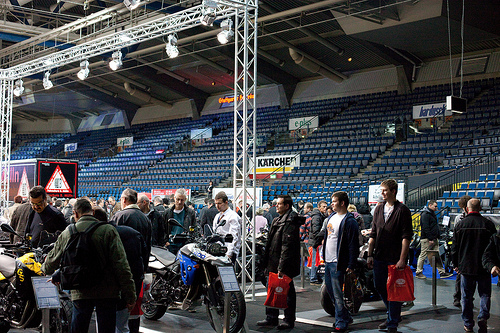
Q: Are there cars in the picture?
A: No, there are no cars.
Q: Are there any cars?
A: No, there are no cars.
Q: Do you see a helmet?
A: No, there are no helmets.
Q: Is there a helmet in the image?
A: No, there are no helmets.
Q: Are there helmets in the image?
A: No, there are no helmets.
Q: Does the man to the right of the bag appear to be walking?
A: Yes, the man is walking.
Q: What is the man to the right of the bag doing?
A: The man is walking.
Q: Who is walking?
A: The man is walking.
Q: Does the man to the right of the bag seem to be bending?
A: No, the man is walking.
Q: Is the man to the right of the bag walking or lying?
A: The man is walking.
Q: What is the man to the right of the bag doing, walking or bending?
A: The man is walking.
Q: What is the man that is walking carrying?
A: The man is carrying a bag.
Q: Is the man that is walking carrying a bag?
A: Yes, the man is carrying a bag.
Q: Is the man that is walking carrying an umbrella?
A: No, the man is carrying a bag.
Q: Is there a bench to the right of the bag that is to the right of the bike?
A: No, there is a man to the right of the bag.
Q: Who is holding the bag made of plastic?
A: The man is holding the bag.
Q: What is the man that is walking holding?
A: The man is holding the bag.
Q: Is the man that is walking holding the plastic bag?
A: Yes, the man is holding the bag.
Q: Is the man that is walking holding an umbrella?
A: No, the man is holding the bag.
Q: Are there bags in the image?
A: Yes, there is a bag.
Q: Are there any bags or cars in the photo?
A: Yes, there is a bag.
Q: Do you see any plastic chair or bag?
A: Yes, there is a plastic bag.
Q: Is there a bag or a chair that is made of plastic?
A: Yes, the bag is made of plastic.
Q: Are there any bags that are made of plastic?
A: Yes, there is a bag that is made of plastic.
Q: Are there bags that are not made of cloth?
A: Yes, there is a bag that is made of plastic.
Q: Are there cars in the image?
A: No, there are no cars.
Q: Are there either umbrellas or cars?
A: No, there are no cars or umbrellas.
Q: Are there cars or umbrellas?
A: No, there are no cars or umbrellas.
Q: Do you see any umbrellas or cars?
A: No, there are no cars or umbrellas.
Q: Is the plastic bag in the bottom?
A: Yes, the bag is in the bottom of the image.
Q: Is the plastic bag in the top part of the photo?
A: No, the bag is in the bottom of the image.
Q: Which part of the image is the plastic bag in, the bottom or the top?
A: The bag is in the bottom of the image.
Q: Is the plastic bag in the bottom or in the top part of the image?
A: The bag is in the bottom of the image.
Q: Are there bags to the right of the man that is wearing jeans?
A: Yes, there is a bag to the right of the man.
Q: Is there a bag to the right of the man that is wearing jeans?
A: Yes, there is a bag to the right of the man.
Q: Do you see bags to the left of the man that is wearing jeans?
A: No, the bag is to the right of the man.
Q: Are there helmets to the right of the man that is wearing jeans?
A: No, there is a bag to the right of the man.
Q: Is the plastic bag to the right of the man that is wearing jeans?
A: Yes, the bag is to the right of the man.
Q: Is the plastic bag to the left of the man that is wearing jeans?
A: No, the bag is to the right of the man.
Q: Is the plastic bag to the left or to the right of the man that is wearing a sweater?
A: The bag is to the right of the man.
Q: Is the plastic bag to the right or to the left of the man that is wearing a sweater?
A: The bag is to the right of the man.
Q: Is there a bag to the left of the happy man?
A: No, the bag is to the right of the man.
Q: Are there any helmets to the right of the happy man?
A: No, there is a bag to the right of the man.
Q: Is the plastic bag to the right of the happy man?
A: Yes, the bag is to the right of the man.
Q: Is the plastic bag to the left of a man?
A: No, the bag is to the right of a man.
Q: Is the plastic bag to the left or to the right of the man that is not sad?
A: The bag is to the right of the man.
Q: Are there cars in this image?
A: No, there are no cars.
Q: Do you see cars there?
A: No, there are no cars.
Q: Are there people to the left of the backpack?
A: Yes, there are people to the left of the backpack.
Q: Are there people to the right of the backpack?
A: No, the people are to the left of the backpack.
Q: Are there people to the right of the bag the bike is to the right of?
A: No, the people are to the left of the backpack.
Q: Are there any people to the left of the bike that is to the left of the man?
A: Yes, there are people to the left of the bike.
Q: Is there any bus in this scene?
A: No, there are no buses.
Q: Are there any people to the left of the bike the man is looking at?
A: Yes, there is a person to the left of the bike.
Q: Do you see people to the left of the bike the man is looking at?
A: Yes, there is a person to the left of the bike.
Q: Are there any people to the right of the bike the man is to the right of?
A: No, the person is to the left of the bike.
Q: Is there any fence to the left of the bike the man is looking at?
A: No, there is a person to the left of the bike.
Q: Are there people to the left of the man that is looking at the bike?
A: Yes, there is a person to the left of the man.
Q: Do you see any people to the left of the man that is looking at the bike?
A: Yes, there is a person to the left of the man.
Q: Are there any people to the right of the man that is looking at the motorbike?
A: No, the person is to the left of the man.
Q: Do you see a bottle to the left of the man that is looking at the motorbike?
A: No, there is a person to the left of the man.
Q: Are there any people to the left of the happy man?
A: Yes, there is a person to the left of the man.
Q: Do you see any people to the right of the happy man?
A: No, the person is to the left of the man.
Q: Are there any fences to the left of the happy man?
A: No, there is a person to the left of the man.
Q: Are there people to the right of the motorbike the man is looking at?
A: Yes, there is a person to the right of the motorcycle.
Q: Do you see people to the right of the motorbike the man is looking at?
A: Yes, there is a person to the right of the motorcycle.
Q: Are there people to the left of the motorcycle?
A: No, the person is to the right of the motorcycle.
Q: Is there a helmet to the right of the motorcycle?
A: No, there is a person to the right of the motorcycle.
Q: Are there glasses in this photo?
A: No, there are no glasses.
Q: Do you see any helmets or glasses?
A: No, there are no glasses or helmets.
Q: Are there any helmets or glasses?
A: No, there are no glasses or helmets.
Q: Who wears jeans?
A: The man wears jeans.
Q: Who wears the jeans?
A: The man wears jeans.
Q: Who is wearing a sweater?
A: The man is wearing a sweater.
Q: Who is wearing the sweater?
A: The man is wearing a sweater.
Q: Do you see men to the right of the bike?
A: Yes, there is a man to the right of the bike.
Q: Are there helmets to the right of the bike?
A: No, there is a man to the right of the bike.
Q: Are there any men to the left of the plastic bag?
A: Yes, there is a man to the left of the bag.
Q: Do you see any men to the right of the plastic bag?
A: No, the man is to the left of the bag.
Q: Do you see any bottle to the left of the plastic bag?
A: No, there is a man to the left of the bag.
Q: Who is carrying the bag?
A: The man is carrying the bag.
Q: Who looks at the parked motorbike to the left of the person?
A: The man looks at the motorcycle.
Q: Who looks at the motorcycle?
A: The man looks at the motorcycle.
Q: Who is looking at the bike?
A: The man is looking at the bike.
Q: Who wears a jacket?
A: The man wears a jacket.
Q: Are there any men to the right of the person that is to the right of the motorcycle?
A: Yes, there is a man to the right of the person.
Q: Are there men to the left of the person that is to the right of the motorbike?
A: No, the man is to the right of the person.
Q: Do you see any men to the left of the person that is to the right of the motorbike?
A: No, the man is to the right of the person.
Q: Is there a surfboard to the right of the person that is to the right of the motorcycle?
A: No, there is a man to the right of the person.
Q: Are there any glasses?
A: No, there are no glasses.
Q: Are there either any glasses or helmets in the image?
A: No, there are no glasses or helmets.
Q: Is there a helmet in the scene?
A: No, there are no helmets.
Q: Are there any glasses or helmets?
A: No, there are no helmets or glasses.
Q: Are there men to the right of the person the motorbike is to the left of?
A: Yes, there is a man to the right of the person.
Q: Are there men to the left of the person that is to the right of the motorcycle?
A: No, the man is to the right of the person.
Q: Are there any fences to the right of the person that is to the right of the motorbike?
A: No, there is a man to the right of the person.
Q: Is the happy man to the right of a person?
A: Yes, the man is to the right of a person.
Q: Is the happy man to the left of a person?
A: No, the man is to the right of a person.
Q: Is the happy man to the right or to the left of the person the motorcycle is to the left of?
A: The man is to the right of the person.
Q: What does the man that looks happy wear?
A: The man wears a jacket.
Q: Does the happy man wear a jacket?
A: Yes, the man wears a jacket.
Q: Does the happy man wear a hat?
A: No, the man wears a jacket.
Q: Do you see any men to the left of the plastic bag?
A: Yes, there is a man to the left of the bag.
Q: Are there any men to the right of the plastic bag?
A: No, the man is to the left of the bag.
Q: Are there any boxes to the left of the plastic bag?
A: No, there is a man to the left of the bag.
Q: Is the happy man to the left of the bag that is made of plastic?
A: Yes, the man is to the left of the bag.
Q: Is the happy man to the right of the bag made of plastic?
A: No, the man is to the left of the bag.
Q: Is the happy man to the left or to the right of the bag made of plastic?
A: The man is to the left of the bag.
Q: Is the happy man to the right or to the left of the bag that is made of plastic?
A: The man is to the left of the bag.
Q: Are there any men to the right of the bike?
A: Yes, there is a man to the right of the bike.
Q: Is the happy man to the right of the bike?
A: Yes, the man is to the right of the bike.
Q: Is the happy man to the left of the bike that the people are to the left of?
A: No, the man is to the right of the bike.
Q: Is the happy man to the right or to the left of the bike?
A: The man is to the right of the bike.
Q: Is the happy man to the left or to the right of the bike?
A: The man is to the right of the bike.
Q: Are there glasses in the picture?
A: No, there are no glasses.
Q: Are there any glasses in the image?
A: No, there are no glasses.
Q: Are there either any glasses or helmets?
A: No, there are no glasses or helmets.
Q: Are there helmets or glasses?
A: No, there are no glasses or helmets.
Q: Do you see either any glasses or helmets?
A: No, there are no glasses or helmets.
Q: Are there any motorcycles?
A: Yes, there is a motorcycle.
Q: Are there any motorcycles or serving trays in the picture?
A: Yes, there is a motorcycle.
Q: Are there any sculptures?
A: No, there are no sculptures.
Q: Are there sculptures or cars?
A: No, there are no sculptures or cars.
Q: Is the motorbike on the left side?
A: Yes, the motorbike is on the left of the image.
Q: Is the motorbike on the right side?
A: No, the motorbike is on the left of the image.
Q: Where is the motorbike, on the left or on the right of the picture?
A: The motorbike is on the left of the image.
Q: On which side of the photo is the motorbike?
A: The motorbike is on the left of the image.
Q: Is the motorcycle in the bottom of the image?
A: Yes, the motorcycle is in the bottom of the image.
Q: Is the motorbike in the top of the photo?
A: No, the motorbike is in the bottom of the image.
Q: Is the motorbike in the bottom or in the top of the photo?
A: The motorbike is in the bottom of the image.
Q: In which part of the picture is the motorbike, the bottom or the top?
A: The motorbike is in the bottom of the image.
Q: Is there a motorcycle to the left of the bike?
A: Yes, there is a motorcycle to the left of the bike.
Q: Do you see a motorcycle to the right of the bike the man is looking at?
A: No, the motorcycle is to the left of the bike.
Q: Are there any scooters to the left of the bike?
A: No, there is a motorcycle to the left of the bike.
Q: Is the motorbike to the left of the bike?
A: Yes, the motorbike is to the left of the bike.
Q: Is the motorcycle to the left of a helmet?
A: No, the motorcycle is to the left of the bike.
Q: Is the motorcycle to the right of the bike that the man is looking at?
A: No, the motorcycle is to the left of the bike.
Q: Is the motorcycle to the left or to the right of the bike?
A: The motorcycle is to the left of the bike.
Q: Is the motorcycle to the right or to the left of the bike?
A: The motorcycle is to the left of the bike.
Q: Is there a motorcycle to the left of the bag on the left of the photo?
A: Yes, there is a motorcycle to the left of the backpack.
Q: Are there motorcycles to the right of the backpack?
A: No, the motorcycle is to the left of the backpack.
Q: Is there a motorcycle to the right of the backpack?
A: No, the motorcycle is to the left of the backpack.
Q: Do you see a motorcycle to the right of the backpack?
A: No, the motorcycle is to the left of the backpack.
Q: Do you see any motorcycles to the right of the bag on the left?
A: No, the motorcycle is to the left of the backpack.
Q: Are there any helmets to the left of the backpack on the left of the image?
A: No, there is a motorcycle to the left of the backpack.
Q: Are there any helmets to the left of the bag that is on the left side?
A: No, there is a motorcycle to the left of the backpack.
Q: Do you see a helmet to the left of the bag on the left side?
A: No, there is a motorcycle to the left of the backpack.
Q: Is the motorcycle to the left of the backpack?
A: Yes, the motorcycle is to the left of the backpack.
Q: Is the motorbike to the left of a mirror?
A: No, the motorbike is to the left of the backpack.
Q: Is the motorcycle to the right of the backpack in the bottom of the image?
A: No, the motorcycle is to the left of the backpack.